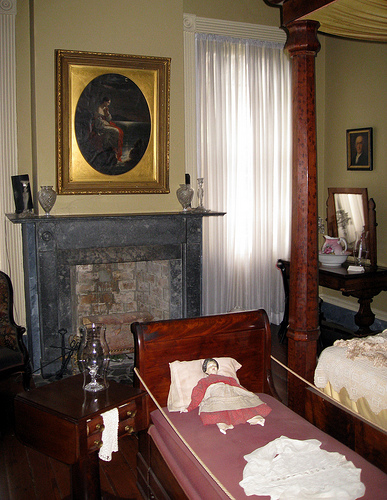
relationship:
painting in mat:
[76, 73, 151, 172] [53, 50, 171, 193]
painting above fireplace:
[76, 73, 151, 172] [13, 214, 213, 378]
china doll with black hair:
[174, 348, 271, 441] [197, 351, 216, 367]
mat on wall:
[53, 50, 171, 193] [33, 0, 186, 55]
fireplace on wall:
[4, 209, 226, 388] [2, 1, 385, 375]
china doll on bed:
[179, 354, 270, 435] [118, 295, 325, 478]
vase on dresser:
[74, 317, 112, 402] [13, 368, 149, 500]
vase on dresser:
[315, 232, 350, 272] [131, 431, 149, 498]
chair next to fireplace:
[2, 268, 39, 403] [68, 245, 194, 359]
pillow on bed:
[166, 356, 242, 411] [130, 309, 385, 498]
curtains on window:
[194, 33, 296, 318] [194, 27, 310, 328]